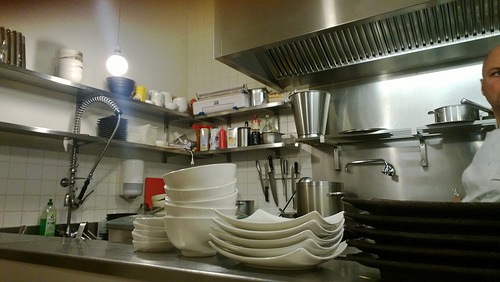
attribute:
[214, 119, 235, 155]
bottle — red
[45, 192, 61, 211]
tope — green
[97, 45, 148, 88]
light — white, hanging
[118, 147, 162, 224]
dispenser — grey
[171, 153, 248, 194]
bowl — white, large, pilked, stacked, white], here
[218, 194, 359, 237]
plate — white, square, piled, curved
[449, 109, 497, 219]
coat — white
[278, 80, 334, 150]
pot — metal, silver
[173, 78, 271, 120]
wrap — here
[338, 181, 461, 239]
plate — brown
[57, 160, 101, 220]
faucet — here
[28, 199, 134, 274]
sink — here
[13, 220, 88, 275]
counter — steel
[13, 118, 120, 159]
shelf — stainless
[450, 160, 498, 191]
uniform — white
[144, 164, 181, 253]
cutting board — red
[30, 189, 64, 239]
dish soap — green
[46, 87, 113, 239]
hose — silver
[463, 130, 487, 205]
shirt — white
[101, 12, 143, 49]
cord — here